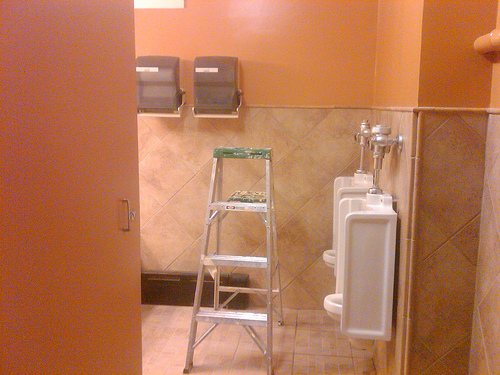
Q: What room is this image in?
A: It is at the bathroom.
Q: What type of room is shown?
A: It is a bathroom.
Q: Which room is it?
A: It is a bathroom.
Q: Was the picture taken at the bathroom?
A: Yes, it was taken in the bathroom.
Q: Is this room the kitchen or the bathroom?
A: It is the bathroom.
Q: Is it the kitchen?
A: No, it is the bathroom.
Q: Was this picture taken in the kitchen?
A: No, the picture was taken in the bathroom.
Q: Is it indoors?
A: Yes, it is indoors.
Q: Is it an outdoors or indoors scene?
A: It is indoors.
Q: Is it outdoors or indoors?
A: It is indoors.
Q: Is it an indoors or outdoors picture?
A: It is indoors.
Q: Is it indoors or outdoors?
A: It is indoors.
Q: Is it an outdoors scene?
A: No, it is indoors.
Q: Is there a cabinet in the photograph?
A: No, there are no cabinets.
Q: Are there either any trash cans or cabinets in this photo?
A: No, there are no cabinets or trash cans.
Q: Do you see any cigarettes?
A: No, there are no cigarettes.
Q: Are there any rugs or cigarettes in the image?
A: No, there are no cigarettes or rugs.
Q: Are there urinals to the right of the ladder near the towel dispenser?
A: Yes, there is a urinal to the right of the ladder.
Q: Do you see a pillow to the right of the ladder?
A: No, there is a urinal to the right of the ladder.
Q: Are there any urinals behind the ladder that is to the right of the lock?
A: Yes, there is a urinal behind the ladder.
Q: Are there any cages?
A: No, there are no cages.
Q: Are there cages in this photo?
A: No, there are no cages.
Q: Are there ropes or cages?
A: No, there are no cages or ropes.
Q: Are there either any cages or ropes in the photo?
A: No, there are no cages or ropes.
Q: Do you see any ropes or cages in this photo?
A: No, there are no cages or ropes.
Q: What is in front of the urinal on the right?
A: The ladder is in front of the urinal.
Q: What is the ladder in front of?
A: The ladder is in front of the urinal.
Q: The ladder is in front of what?
A: The ladder is in front of the urinal.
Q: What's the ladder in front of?
A: The ladder is in front of the urinal.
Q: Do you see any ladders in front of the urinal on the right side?
A: Yes, there is a ladder in front of the urinal.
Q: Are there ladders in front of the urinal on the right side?
A: Yes, there is a ladder in front of the urinal.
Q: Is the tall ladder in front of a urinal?
A: Yes, the ladder is in front of a urinal.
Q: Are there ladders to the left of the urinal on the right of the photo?
A: Yes, there is a ladder to the left of the urinal.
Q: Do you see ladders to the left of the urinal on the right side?
A: Yes, there is a ladder to the left of the urinal.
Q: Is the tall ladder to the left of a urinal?
A: Yes, the ladder is to the left of a urinal.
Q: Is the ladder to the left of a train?
A: No, the ladder is to the left of a urinal.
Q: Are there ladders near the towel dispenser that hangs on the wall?
A: Yes, there is a ladder near the towel dispenser.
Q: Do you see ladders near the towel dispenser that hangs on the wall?
A: Yes, there is a ladder near the towel dispenser.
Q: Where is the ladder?
A: The ladder is in the bathroom.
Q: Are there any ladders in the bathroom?
A: Yes, there is a ladder in the bathroom.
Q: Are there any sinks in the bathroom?
A: No, there is a ladder in the bathroom.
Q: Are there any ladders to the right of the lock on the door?
A: Yes, there is a ladder to the right of the lock.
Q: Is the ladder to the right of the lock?
A: Yes, the ladder is to the right of the lock.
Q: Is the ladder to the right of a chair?
A: No, the ladder is to the right of the lock.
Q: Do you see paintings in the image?
A: No, there are no paintings.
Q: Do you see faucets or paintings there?
A: No, there are no paintings or faucets.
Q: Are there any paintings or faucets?
A: No, there are no paintings or faucets.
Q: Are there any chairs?
A: No, there are no chairs.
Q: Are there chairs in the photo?
A: No, there are no chairs.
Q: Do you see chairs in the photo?
A: No, there are no chairs.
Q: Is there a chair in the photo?
A: No, there are no chairs.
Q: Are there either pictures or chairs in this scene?
A: No, there are no chairs or pictures.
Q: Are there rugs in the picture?
A: No, there are no rugs.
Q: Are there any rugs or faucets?
A: No, there are no rugs or faucets.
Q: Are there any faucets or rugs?
A: No, there are no rugs or faucets.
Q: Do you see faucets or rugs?
A: No, there are no rugs or faucets.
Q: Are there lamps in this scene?
A: No, there are no lamps.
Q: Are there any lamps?
A: No, there are no lamps.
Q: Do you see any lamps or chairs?
A: No, there are no lamps or chairs.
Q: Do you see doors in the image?
A: Yes, there is a door.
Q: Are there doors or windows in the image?
A: Yes, there is a door.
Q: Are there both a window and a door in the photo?
A: No, there is a door but no windows.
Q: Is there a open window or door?
A: Yes, there is an open door.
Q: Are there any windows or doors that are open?
A: Yes, the door is open.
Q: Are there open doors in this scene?
A: Yes, there is an open door.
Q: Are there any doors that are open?
A: Yes, there is a door that is open.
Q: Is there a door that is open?
A: Yes, there is a door that is open.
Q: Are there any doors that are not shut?
A: Yes, there is a open door.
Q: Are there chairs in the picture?
A: No, there are no chairs.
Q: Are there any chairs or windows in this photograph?
A: No, there are no chairs or windows.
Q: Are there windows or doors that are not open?
A: No, there is a door but it is open.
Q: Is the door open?
A: Yes, the door is open.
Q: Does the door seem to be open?
A: Yes, the door is open.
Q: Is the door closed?
A: No, the door is open.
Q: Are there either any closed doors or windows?
A: No, there is a door but it is open.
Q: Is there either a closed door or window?
A: No, there is a door but it is open.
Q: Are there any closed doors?
A: No, there is a door but it is open.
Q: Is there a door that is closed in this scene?
A: No, there is a door but it is open.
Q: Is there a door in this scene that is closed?
A: No, there is a door but it is open.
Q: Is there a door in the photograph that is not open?
A: No, there is a door but it is open.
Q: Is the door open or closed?
A: The door is open.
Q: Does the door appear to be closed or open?
A: The door is open.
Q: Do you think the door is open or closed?
A: The door is open.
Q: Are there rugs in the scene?
A: No, there are no rugs.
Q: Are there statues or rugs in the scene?
A: No, there are no rugs or statues.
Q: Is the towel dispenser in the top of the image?
A: Yes, the towel dispenser is in the top of the image.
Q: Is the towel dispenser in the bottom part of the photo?
A: No, the towel dispenser is in the top of the image.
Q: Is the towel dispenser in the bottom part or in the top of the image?
A: The towel dispenser is in the top of the image.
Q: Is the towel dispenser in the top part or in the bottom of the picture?
A: The towel dispenser is in the top of the image.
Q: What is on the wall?
A: The towel dispenser is on the wall.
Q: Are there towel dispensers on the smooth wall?
A: Yes, there is a towel dispenser on the wall.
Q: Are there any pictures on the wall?
A: No, there is a towel dispenser on the wall.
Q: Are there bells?
A: No, there are no bells.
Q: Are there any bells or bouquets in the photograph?
A: No, there are no bells or bouquets.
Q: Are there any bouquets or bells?
A: No, there are no bells or bouquets.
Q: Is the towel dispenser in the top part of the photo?
A: Yes, the towel dispenser is in the top of the image.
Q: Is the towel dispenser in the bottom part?
A: No, the towel dispenser is in the top of the image.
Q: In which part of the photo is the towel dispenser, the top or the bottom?
A: The towel dispenser is in the top of the image.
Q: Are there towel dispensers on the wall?
A: Yes, there is a towel dispenser on the wall.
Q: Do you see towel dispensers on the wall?
A: Yes, there is a towel dispenser on the wall.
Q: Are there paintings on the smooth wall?
A: No, there is a towel dispenser on the wall.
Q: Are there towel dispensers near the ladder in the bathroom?
A: Yes, there is a towel dispenser near the ladder.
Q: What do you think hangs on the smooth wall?
A: The towel dispenser hangs on the wall.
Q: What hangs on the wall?
A: The towel dispenser hangs on the wall.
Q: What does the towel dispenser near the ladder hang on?
A: The towel dispenser hangs on the wall.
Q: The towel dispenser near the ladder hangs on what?
A: The towel dispenser hangs on the wall.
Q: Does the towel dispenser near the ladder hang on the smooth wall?
A: Yes, the towel dispenser hangs on the wall.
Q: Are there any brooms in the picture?
A: No, there are no brooms.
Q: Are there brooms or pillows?
A: No, there are no brooms or pillows.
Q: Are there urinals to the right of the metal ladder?
A: Yes, there is a urinal to the right of the ladder.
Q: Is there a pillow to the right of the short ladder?
A: No, there is a urinal to the right of the ladder.